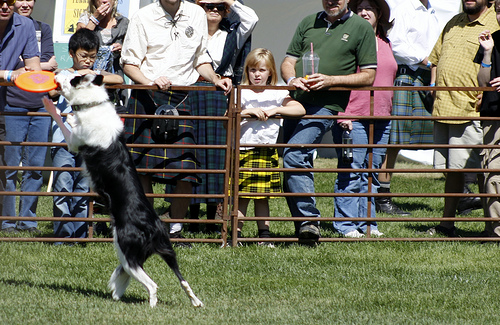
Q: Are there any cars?
A: No, there are no cars.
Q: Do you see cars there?
A: No, there are no cars.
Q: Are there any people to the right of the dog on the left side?
A: Yes, there is a person to the right of the dog.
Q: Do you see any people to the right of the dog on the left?
A: Yes, there is a person to the right of the dog.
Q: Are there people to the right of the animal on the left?
A: Yes, there is a person to the right of the dog.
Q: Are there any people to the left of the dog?
A: No, the person is to the right of the dog.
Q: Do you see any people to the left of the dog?
A: No, the person is to the right of the dog.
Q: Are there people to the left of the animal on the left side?
A: No, the person is to the right of the dog.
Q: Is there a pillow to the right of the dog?
A: No, there is a person to the right of the dog.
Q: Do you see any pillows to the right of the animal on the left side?
A: No, there is a person to the right of the dog.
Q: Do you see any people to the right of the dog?
A: Yes, there is a person to the right of the dog.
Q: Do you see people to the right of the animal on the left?
A: Yes, there is a person to the right of the dog.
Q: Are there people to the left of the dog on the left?
A: No, the person is to the right of the dog.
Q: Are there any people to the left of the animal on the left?
A: No, the person is to the right of the dog.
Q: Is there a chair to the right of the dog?
A: No, there is a person to the right of the dog.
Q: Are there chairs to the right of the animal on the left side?
A: No, there is a person to the right of the dog.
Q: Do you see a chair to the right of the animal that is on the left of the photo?
A: No, there is a person to the right of the dog.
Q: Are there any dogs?
A: Yes, there is a dog.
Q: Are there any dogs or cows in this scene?
A: Yes, there is a dog.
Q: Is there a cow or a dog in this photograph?
A: Yes, there is a dog.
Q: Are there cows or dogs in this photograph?
A: Yes, there is a dog.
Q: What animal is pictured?
A: The animal is a dog.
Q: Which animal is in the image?
A: The animal is a dog.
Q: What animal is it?
A: The animal is a dog.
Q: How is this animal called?
A: This is a dog.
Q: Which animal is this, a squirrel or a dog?
A: This is a dog.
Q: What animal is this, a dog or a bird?
A: This is a dog.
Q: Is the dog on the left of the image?
A: Yes, the dog is on the left of the image.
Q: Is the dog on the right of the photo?
A: No, the dog is on the left of the image.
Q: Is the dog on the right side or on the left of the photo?
A: The dog is on the left of the image.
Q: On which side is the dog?
A: The dog is on the left of the image.